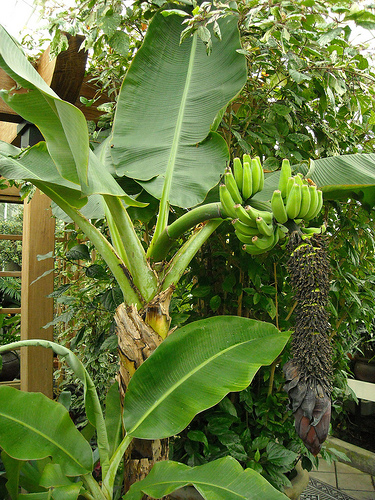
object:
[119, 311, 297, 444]
banana leaf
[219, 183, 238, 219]
bananas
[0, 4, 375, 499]
banana tree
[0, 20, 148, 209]
leaves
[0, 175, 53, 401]
structure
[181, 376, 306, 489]
plants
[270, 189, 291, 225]
banana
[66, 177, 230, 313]
branches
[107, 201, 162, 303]
stalk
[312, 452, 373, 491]
tile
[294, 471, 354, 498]
rug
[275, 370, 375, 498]
ground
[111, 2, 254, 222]
leaves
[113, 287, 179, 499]
trunk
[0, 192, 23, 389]
rungs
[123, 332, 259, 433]
stripe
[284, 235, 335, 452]
banana flower